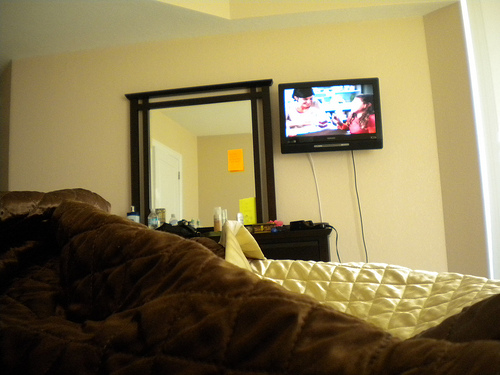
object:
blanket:
[217, 220, 500, 341]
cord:
[305, 153, 321, 221]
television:
[277, 77, 383, 155]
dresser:
[148, 221, 332, 263]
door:
[153, 145, 179, 223]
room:
[0, 0, 499, 374]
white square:
[406, 270, 436, 286]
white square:
[325, 265, 356, 283]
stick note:
[237, 197, 259, 225]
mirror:
[122, 78, 276, 236]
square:
[379, 269, 410, 285]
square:
[367, 297, 399, 314]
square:
[446, 291, 476, 312]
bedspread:
[0, 186, 499, 374]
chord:
[350, 151, 368, 264]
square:
[323, 280, 355, 302]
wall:
[6, 17, 446, 275]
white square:
[349, 281, 378, 303]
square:
[421, 291, 452, 309]